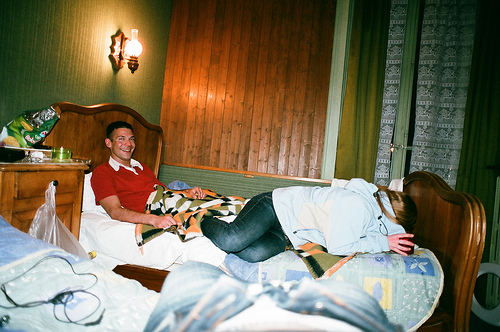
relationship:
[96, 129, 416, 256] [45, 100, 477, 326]
couple in bed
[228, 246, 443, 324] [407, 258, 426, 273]
blanket has butterfly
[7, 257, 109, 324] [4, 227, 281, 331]
cord on top of bed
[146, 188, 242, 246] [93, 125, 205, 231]
quilt on lap of man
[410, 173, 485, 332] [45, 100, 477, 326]
footboard of bed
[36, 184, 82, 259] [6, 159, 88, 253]
bag hanging on nightstand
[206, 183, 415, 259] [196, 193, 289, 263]
woman wearing jeans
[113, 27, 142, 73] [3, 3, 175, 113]
light on side of wall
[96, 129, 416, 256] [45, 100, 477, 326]
couple on top of bed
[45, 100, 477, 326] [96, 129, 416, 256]
bed with couple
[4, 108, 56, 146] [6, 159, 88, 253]
bag on top of nightstand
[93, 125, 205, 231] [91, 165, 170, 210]
man wearing shirt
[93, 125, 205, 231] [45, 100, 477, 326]
man in bed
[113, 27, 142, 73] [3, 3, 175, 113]
light mounted to wall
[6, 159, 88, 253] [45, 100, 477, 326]
nightstand next to bed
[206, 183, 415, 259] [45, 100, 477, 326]
woman lying on bed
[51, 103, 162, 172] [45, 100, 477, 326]
headboard of bed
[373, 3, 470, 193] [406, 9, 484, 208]
drapes on front of door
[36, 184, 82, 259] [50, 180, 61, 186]
bag hanging on knob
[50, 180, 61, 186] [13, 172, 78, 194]
knob on front of drawer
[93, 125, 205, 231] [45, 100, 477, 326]
man lying on bed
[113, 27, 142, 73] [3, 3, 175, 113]
light mounted on wall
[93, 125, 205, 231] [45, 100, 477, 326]
man laying in bed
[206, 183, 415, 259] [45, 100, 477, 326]
woman laying in bed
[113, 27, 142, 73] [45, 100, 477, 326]
light over bed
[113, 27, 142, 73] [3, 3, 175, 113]
light hanging on wall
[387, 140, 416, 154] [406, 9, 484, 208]
knob on front of door